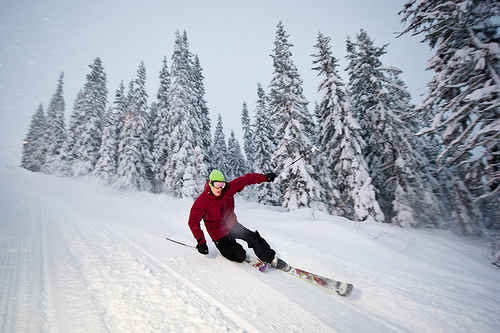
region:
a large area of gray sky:
[0, 0, 498, 167]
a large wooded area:
[18, 0, 498, 267]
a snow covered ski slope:
[0, 165, 499, 332]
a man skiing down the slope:
[187, 169, 287, 269]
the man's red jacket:
[187, 173, 267, 245]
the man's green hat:
[207, 169, 224, 186]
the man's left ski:
[283, 266, 352, 296]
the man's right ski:
[244, 255, 271, 272]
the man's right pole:
[164, 236, 207, 253]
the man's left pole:
[267, 147, 314, 180]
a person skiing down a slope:
[170, 168, 354, 297]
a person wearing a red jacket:
[186, 168, 279, 269]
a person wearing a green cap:
[187, 166, 280, 270]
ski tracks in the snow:
[6, 175, 160, 331]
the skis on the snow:
[241, 252, 354, 298]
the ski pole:
[161, 237, 207, 249]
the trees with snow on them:
[12, 34, 207, 194]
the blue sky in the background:
[3, 3, 164, 53]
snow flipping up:
[21, 134, 148, 213]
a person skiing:
[176, 168, 354, 297]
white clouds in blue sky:
[27, 16, 66, 36]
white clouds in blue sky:
[84, 3, 142, 57]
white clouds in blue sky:
[218, 15, 245, 56]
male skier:
[162, 160, 284, 285]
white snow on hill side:
[25, 215, 77, 250]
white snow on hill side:
[91, 196, 142, 243]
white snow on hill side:
[50, 251, 106, 301]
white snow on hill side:
[126, 273, 208, 323]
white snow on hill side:
[391, 266, 463, 306]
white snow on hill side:
[329, 241, 375, 262]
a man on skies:
[157, 152, 353, 300]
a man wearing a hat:
[205, 166, 227, 185]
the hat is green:
[199, 161, 228, 182]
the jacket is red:
[182, 166, 268, 242]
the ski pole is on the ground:
[156, 227, 195, 252]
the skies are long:
[227, 247, 361, 294]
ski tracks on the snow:
[34, 145, 218, 330]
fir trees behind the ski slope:
[15, 3, 498, 244]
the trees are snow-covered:
[20, 16, 497, 238]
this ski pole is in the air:
[251, 141, 325, 187]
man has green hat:
[199, 158, 234, 199]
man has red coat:
[161, 170, 251, 252]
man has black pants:
[195, 224, 274, 280]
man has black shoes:
[273, 237, 289, 304]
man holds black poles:
[152, 131, 372, 295]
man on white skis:
[223, 237, 380, 313]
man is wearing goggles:
[198, 172, 233, 199]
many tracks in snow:
[46, 181, 167, 323]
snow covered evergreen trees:
[61, 59, 495, 238]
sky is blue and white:
[178, 3, 271, 63]